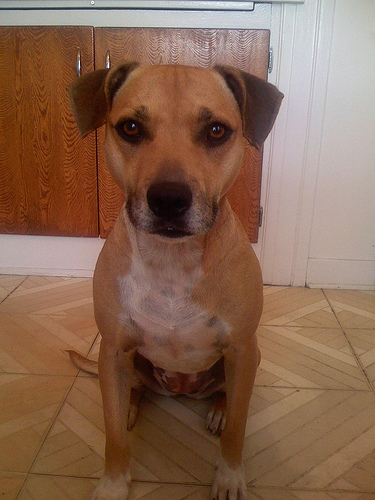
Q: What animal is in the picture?
A: A dog.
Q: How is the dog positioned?
A: Sitting on the dogs hindlegs.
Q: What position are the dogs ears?
A: Hanging down.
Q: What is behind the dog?
A: Brown cupboards.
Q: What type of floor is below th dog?
A: A diagnally designed wooden tile.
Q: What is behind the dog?
A: A white wall.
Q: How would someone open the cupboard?
A: With the metal handle.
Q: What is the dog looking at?
A: The camera.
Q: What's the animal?
A: Dog.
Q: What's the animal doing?
A: Sitting.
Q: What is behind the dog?
A: Wooden doors.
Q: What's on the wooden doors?
A: Handles.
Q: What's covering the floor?
A: Tiles.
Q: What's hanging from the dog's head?
A: Ears.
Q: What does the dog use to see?
A: Eyes.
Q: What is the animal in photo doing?
A: Sitting.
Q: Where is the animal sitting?
A: Floor.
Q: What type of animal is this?
A: Dog.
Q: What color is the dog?
A: Light brown.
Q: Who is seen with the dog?
A: Noone.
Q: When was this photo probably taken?
A: Daytime.